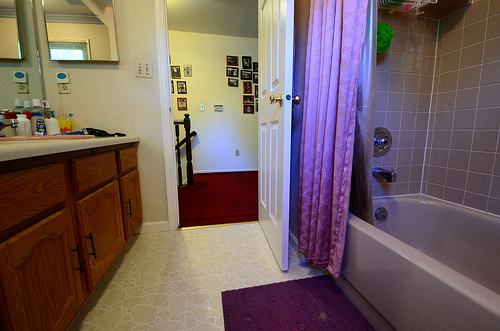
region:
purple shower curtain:
[305, 2, 359, 268]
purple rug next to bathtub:
[218, 269, 383, 329]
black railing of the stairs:
[175, 116, 197, 187]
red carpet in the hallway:
[180, 161, 256, 221]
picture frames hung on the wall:
[173, 50, 258, 122]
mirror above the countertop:
[36, 2, 134, 67]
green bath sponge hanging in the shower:
[373, 19, 395, 50]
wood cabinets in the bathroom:
[3, 148, 140, 323]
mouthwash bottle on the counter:
[30, 98, 45, 132]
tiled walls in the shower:
[368, 21, 497, 200]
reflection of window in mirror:
[36, 0, 126, 80]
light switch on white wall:
[120, 18, 160, 123]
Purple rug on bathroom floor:
[217, 238, 384, 328]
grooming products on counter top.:
[3, 65, 81, 140]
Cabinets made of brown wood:
[0, 122, 141, 322]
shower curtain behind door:
[263, 18, 356, 281]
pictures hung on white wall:
[197, 32, 287, 148]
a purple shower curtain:
[305, 2, 393, 285]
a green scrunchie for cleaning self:
[370, 20, 402, 65]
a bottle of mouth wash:
[25, 93, 55, 148]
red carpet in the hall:
[178, 159, 279, 224]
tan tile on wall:
[375, 17, 498, 207]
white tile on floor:
[40, 232, 342, 329]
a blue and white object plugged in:
[51, 65, 72, 87]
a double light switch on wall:
[125, 48, 154, 94]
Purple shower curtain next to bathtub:
[298, 0, 370, 281]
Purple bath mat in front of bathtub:
[219, 272, 375, 329]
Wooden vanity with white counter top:
[0, 140, 140, 330]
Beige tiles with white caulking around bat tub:
[374, 3, 499, 215]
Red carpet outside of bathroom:
[180, 172, 259, 227]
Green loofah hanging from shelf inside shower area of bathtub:
[376, 23, 391, 55]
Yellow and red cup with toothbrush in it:
[61, 111, 73, 131]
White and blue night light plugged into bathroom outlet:
[55, 71, 70, 93]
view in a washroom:
[1, 26, 153, 324]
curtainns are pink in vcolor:
[288, 12, 347, 244]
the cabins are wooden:
[23, 173, 129, 273]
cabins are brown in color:
[29, 162, 121, 284]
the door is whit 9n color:
[250, 19, 290, 259]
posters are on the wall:
[221, 24, 261, 139]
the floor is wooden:
[233, 165, 258, 214]